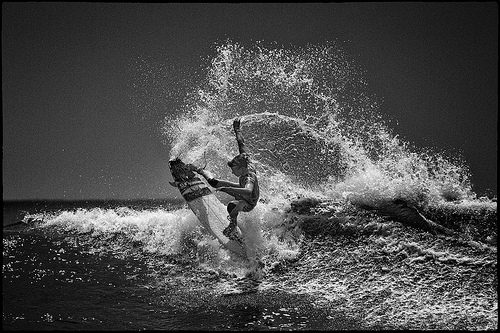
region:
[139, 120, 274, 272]
person surfing in ocean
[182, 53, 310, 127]
water spraying in air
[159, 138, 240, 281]
white and black surfboard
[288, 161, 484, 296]
large ocean wave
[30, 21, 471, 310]
black and white picture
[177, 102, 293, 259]
person's arms in air for balance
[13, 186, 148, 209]
horizon line where ocean meets sky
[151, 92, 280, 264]
persons feet attached to surfboard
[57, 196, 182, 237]
ocean waves causing white caps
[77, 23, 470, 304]
only one person in picture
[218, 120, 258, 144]
right hand of surfer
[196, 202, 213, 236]
white surfboard in water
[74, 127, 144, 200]
dark gray skies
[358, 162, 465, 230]
waves that were ridden by rider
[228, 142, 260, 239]
surfer along ocean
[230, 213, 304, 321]
white waves being ridden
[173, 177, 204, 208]
tip of surfboard of rider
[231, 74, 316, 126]
airborne waves as a result of surfboard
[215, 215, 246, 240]
left foot of surfboarder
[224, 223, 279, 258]
logo of surfboard tough to see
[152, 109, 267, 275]
a surfer riding a wave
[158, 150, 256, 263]
a striped surfboard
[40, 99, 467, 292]
a crashing wave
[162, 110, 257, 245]
a man doing a surfing trick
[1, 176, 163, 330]
an ocean with waves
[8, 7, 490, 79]
clear skies above the ocean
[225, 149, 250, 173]
hairstyle with front flipped up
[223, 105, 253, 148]
a hand reaching toward the sky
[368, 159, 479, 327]
rippled water in the ocean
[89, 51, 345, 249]
white foam of a wave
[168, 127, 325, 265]
A surfer on a surf board.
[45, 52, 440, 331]
This picture is in black and white.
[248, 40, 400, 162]
Spray of water from surf board.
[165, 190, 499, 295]
A wave in the water.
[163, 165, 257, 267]
Surfboard is white with stripes.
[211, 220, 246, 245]
This foot is balanced on the surfboard.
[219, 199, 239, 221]
A black knee pad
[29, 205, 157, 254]
Foam from the wave.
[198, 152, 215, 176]
String attached to angle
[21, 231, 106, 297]
Light reflecting on water.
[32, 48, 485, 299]
Black and white picture.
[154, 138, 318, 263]
One man is surfing.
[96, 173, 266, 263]
waves are white color.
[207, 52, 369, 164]
Water is splashing.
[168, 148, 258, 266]
Surfing board is white color.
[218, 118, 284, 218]
Man is stretching hands to get balance.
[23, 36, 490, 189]
Sky is clear with no clouds.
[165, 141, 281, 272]
One surfing boat is seen.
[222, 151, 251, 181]
Man is wearing cap on his head.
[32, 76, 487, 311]
Picture is taken in beach.